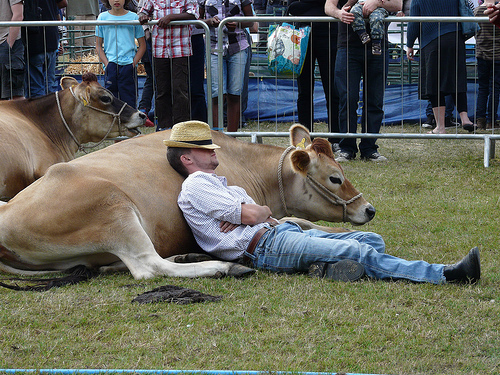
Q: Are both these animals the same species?
A: Yes, all the animals are cows.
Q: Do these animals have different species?
A: No, all the animals are cows.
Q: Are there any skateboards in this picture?
A: No, there are no skateboards.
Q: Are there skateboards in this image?
A: No, there are no skateboards.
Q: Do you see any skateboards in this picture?
A: No, there are no skateboards.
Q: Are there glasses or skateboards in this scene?
A: No, there are no skateboards or glasses.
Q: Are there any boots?
A: Yes, there are boots.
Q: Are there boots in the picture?
A: Yes, there are boots.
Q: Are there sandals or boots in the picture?
A: Yes, there are boots.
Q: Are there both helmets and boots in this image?
A: No, there are boots but no helmets.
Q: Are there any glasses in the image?
A: No, there are no glasses.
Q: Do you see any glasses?
A: No, there are no glasses.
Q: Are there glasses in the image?
A: No, there are no glasses.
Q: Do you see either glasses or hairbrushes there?
A: No, there are no glasses or hairbrushes.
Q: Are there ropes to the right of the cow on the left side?
A: Yes, there is a rope to the right of the cow.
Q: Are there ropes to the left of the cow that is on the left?
A: No, the rope is to the right of the cow.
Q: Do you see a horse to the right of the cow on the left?
A: No, there is a rope to the right of the cow.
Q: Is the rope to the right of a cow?
A: Yes, the rope is to the right of a cow.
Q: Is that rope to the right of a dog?
A: No, the rope is to the right of a cow.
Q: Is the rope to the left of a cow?
A: No, the rope is to the right of a cow.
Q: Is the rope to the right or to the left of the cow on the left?
A: The rope is to the right of the cow.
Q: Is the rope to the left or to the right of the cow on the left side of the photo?
A: The rope is to the right of the cow.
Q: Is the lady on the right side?
A: Yes, the lady is on the right of the image.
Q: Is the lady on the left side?
A: No, the lady is on the right of the image.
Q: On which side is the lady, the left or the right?
A: The lady is on the right of the image.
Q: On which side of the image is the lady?
A: The lady is on the right of the image.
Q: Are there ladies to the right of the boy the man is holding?
A: Yes, there is a lady to the right of the boy.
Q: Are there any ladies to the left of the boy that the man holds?
A: No, the lady is to the right of the boy.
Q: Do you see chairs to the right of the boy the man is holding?
A: No, there is a lady to the right of the boy.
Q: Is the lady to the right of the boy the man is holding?
A: Yes, the lady is to the right of the boy.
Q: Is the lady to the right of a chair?
A: No, the lady is to the right of the boy.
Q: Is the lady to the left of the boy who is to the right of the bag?
A: No, the lady is to the right of the boy.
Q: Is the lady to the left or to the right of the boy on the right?
A: The lady is to the right of the boy.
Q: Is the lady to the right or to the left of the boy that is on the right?
A: The lady is to the right of the boy.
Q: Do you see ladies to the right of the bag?
A: Yes, there is a lady to the right of the bag.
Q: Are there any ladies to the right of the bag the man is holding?
A: Yes, there is a lady to the right of the bag.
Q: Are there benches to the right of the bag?
A: No, there is a lady to the right of the bag.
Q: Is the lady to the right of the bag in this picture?
A: Yes, the lady is to the right of the bag.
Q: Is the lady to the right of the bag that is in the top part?
A: Yes, the lady is to the right of the bag.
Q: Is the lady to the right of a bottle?
A: No, the lady is to the right of the bag.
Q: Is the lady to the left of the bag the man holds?
A: No, the lady is to the right of the bag.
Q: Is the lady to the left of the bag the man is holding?
A: No, the lady is to the right of the bag.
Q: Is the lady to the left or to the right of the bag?
A: The lady is to the right of the bag.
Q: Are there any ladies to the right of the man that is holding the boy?
A: Yes, there is a lady to the right of the man.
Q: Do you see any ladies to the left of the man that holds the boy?
A: No, the lady is to the right of the man.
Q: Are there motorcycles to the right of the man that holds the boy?
A: No, there is a lady to the right of the man.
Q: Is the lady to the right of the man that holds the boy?
A: Yes, the lady is to the right of the man.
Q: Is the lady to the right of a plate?
A: No, the lady is to the right of the man.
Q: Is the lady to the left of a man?
A: No, the lady is to the right of a man.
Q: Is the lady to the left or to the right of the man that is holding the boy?
A: The lady is to the right of the man.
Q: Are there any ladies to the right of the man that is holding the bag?
A: Yes, there is a lady to the right of the man.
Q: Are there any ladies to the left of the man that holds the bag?
A: No, the lady is to the right of the man.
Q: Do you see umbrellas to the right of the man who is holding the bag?
A: No, there is a lady to the right of the man.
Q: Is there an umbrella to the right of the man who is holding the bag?
A: No, there is a lady to the right of the man.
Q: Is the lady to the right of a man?
A: Yes, the lady is to the right of a man.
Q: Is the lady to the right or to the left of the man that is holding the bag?
A: The lady is to the right of the man.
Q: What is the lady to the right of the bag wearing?
A: The lady is wearing a shirt.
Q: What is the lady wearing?
A: The lady is wearing a shirt.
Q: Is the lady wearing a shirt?
A: Yes, the lady is wearing a shirt.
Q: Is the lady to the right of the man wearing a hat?
A: No, the lady is wearing a shirt.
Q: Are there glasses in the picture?
A: No, there are no glasses.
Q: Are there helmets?
A: No, there are no helmets.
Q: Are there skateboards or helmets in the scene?
A: No, there are no helmets or skateboards.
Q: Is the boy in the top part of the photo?
A: Yes, the boy is in the top of the image.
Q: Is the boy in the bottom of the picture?
A: No, the boy is in the top of the image.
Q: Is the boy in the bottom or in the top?
A: The boy is in the top of the image.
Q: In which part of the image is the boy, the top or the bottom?
A: The boy is in the top of the image.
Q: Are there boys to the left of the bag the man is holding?
A: Yes, there is a boy to the left of the bag.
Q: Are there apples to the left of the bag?
A: No, there is a boy to the left of the bag.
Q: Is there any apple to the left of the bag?
A: No, there is a boy to the left of the bag.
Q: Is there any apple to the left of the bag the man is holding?
A: No, there is a boy to the left of the bag.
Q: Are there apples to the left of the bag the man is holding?
A: No, there is a boy to the left of the bag.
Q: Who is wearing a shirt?
A: The boy is wearing a shirt.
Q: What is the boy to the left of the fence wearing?
A: The boy is wearing a shirt.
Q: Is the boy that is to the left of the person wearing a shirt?
A: Yes, the boy is wearing a shirt.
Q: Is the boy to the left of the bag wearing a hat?
A: No, the boy is wearing a shirt.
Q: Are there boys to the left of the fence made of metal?
A: Yes, there is a boy to the left of the fence.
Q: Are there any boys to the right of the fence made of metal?
A: No, the boy is to the left of the fence.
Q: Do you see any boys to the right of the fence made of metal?
A: No, the boy is to the left of the fence.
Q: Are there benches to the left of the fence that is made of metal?
A: No, there is a boy to the left of the fence.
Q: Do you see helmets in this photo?
A: No, there are no helmets.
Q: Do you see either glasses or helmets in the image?
A: No, there are no helmets or glasses.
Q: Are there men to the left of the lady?
A: Yes, there is a man to the left of the lady.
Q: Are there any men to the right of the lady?
A: No, the man is to the left of the lady.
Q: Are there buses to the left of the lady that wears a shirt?
A: No, there is a man to the left of the lady.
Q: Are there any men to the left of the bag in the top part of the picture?
A: No, the man is to the right of the bag.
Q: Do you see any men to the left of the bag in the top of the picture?
A: No, the man is to the right of the bag.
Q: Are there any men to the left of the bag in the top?
A: No, the man is to the right of the bag.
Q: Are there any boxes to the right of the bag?
A: No, there is a man to the right of the bag.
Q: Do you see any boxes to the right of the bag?
A: No, there is a man to the right of the bag.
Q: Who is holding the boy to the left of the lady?
A: The man is holding the boy.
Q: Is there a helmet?
A: No, there are no helmets.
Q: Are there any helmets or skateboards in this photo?
A: No, there are no helmets or skateboards.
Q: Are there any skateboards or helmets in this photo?
A: No, there are no helmets or skateboards.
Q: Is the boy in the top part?
A: Yes, the boy is in the top of the image.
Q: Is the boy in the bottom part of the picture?
A: No, the boy is in the top of the image.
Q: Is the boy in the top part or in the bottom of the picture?
A: The boy is in the top of the image.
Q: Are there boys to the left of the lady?
A: Yes, there is a boy to the left of the lady.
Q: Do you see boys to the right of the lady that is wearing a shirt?
A: No, the boy is to the left of the lady.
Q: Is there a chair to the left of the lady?
A: No, there is a boy to the left of the lady.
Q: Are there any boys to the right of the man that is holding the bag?
A: Yes, there is a boy to the right of the man.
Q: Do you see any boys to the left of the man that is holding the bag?
A: No, the boy is to the right of the man.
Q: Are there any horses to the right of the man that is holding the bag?
A: No, there is a boy to the right of the man.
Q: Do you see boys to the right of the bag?
A: Yes, there is a boy to the right of the bag.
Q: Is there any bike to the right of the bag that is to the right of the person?
A: No, there is a boy to the right of the bag.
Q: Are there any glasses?
A: No, there are no glasses.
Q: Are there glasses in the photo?
A: No, there are no glasses.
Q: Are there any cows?
A: Yes, there is a cow.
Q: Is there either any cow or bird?
A: Yes, there is a cow.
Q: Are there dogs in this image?
A: No, there are no dogs.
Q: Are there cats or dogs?
A: No, there are no dogs or cats.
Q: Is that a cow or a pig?
A: That is a cow.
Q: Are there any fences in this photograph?
A: Yes, there is a fence.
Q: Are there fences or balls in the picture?
A: Yes, there is a fence.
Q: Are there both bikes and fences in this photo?
A: No, there is a fence but no bikes.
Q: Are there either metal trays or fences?
A: Yes, there is a metal fence.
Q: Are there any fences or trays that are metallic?
A: Yes, the fence is metallic.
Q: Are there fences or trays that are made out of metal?
A: Yes, the fence is made of metal.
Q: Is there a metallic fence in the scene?
A: Yes, there is a metal fence.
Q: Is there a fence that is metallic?
A: Yes, there is a fence that is metallic.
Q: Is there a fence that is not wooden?
A: Yes, there is a metallic fence.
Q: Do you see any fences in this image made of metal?
A: Yes, there is a fence that is made of metal.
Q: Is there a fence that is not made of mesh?
A: Yes, there is a fence that is made of metal.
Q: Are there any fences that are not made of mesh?
A: Yes, there is a fence that is made of metal.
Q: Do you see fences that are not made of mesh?
A: Yes, there is a fence that is made of metal.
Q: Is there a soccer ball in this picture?
A: No, there are no soccer balls.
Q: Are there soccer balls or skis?
A: No, there are no soccer balls or skis.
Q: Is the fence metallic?
A: Yes, the fence is metallic.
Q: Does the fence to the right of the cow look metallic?
A: Yes, the fence is metallic.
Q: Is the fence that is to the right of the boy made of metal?
A: Yes, the fence is made of metal.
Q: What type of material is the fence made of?
A: The fence is made of metal.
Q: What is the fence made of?
A: The fence is made of metal.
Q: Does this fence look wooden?
A: No, the fence is metallic.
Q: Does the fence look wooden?
A: No, the fence is metallic.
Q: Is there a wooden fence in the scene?
A: No, there is a fence but it is metallic.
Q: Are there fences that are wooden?
A: No, there is a fence but it is metallic.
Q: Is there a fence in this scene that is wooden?
A: No, there is a fence but it is metallic.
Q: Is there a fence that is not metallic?
A: No, there is a fence but it is metallic.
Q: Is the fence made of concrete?
A: No, the fence is made of metal.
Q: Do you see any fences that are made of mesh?
A: No, there is a fence but it is made of metal.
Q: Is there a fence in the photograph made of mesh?
A: No, there is a fence but it is made of metal.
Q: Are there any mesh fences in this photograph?
A: No, there is a fence but it is made of metal.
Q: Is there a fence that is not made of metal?
A: No, there is a fence but it is made of metal.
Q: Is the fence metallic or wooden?
A: The fence is metallic.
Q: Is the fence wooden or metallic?
A: The fence is metallic.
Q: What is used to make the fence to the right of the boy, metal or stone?
A: The fence is made of metal.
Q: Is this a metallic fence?
A: Yes, this is a metallic fence.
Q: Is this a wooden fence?
A: No, this is a metallic fence.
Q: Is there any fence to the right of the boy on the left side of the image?
A: Yes, there is a fence to the right of the boy.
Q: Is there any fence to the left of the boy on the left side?
A: No, the fence is to the right of the boy.